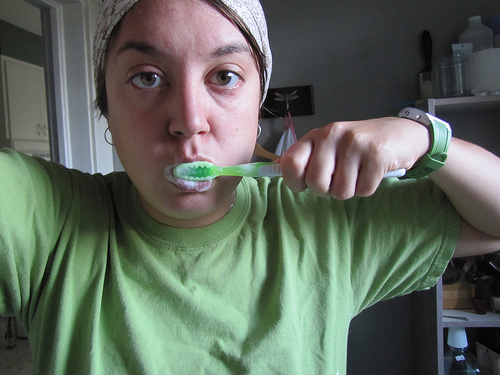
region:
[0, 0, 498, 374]
Woman holding green toothbrush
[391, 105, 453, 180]
Green watch on wrist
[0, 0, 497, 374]
Woman wearing a green shirt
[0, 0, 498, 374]
Woman is brushing her teeth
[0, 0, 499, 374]
Woman wearing a bandana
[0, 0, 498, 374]
Woman wearing hoop earring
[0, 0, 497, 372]
woman brushing her teeth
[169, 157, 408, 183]
toothbrush is white and green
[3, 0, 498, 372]
woman wearing green shirt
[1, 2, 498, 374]
woman wearing a headband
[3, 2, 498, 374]
woman wearing a green watch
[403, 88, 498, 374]
cabinet with shelves behind woman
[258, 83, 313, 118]
dragonfly hook on wall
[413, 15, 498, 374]
bottles on shelves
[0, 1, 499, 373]
woman with hoop earrings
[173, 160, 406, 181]
toothbrush is green and white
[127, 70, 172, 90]
womans eyes are brown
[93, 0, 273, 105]
womans hat is brown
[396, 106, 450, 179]
womans watch is green and white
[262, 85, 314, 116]
picture has a insect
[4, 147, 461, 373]
woman has on a green shirt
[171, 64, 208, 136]
woman has a long nose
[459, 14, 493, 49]
container is white and clear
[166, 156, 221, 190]
woman has a mouth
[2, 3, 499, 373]
woman is brushing her teeth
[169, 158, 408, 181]
green and white toothbrush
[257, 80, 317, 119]
gold dragonfly on dark wood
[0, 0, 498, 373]
woman wearing a white bandana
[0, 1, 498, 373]
woman wearing a green shirt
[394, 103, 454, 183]
rubber green and silver watch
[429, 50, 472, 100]
large clear glass jar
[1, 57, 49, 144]
white cabinets with metal handles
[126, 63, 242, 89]
two hazle eyes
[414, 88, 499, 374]
white wood shelving unit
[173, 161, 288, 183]
green toothbrush in womans hand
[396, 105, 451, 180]
green watch on womans wrist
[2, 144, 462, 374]
green shirt on woman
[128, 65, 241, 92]
two green eyes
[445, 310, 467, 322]
hair pins on shelving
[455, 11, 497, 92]
rubbing alcohol on shelves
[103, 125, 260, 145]
hoop earings hanging from womans ears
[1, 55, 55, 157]
cabinet in the background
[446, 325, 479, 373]
mouthwash on bottom shelf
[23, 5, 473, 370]
this is a woman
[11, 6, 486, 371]
woman brushing her teeth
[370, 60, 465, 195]
a green wrist watch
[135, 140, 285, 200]
the toothbrush is green